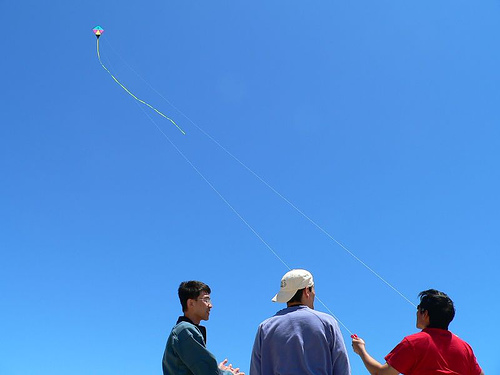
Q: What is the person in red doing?
A: Flying a kite.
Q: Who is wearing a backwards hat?
A: The person in the middle.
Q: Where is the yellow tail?
A: Coming off of the kite.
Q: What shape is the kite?
A: A diamond.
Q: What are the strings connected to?
A: The kite.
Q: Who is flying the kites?
A: Man in red shirt.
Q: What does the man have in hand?
A: Kite string.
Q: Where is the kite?
A: In the air.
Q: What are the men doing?
A: Talking.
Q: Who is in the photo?
A: A group of men.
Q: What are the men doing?
A: Flying a kite.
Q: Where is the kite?
A: In the air.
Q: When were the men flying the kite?
A: During daylight hours.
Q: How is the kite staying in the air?
A: Wind.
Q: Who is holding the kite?
A: The man on the right.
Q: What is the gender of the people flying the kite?
A: Male.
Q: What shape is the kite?
A: Diamond.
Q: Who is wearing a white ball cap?
A: The man in the middle.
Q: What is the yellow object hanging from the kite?
A: The tail.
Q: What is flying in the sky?
A: A kite.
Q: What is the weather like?
A: Nice and clear.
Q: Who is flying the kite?
A: The man in the red shirt.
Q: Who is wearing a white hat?
A: The man in the middle.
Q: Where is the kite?
A: High in the sky.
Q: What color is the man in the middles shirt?
A: Blue.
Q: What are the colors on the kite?
A: Green, red and yellow.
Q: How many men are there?
A: 3.